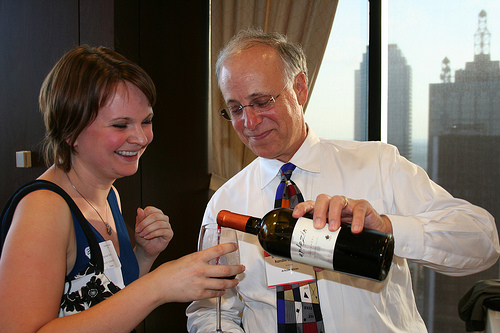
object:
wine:
[256, 213, 394, 273]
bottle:
[217, 207, 394, 281]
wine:
[217, 225, 222, 264]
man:
[185, 27, 499, 332]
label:
[289, 216, 342, 271]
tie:
[273, 161, 319, 333]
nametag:
[265, 251, 319, 288]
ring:
[342, 195, 349, 210]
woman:
[0, 44, 246, 332]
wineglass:
[199, 224, 246, 333]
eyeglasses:
[219, 73, 298, 121]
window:
[208, 1, 499, 333]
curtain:
[209, 1, 340, 198]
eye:
[257, 100, 270, 106]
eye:
[231, 108, 240, 114]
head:
[217, 30, 310, 159]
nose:
[241, 99, 264, 130]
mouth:
[243, 129, 275, 142]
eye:
[113, 121, 127, 129]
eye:
[142, 119, 152, 125]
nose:
[126, 123, 148, 146]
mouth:
[114, 146, 142, 162]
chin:
[114, 164, 140, 176]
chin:
[252, 144, 283, 159]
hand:
[153, 241, 248, 304]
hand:
[136, 206, 174, 256]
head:
[40, 44, 155, 180]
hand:
[292, 194, 388, 233]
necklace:
[63, 165, 112, 235]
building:
[355, 44, 412, 164]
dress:
[0, 178, 141, 332]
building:
[430, 9, 499, 333]